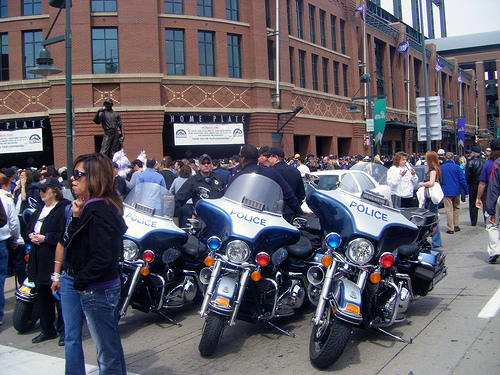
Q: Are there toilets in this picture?
A: No, there are no toilets.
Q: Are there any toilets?
A: No, there are no toilets.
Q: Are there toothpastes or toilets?
A: No, there are no toilets or toothpastes.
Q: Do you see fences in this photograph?
A: No, there are no fences.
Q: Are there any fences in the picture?
A: No, there are no fences.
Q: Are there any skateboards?
A: No, there are no skateboards.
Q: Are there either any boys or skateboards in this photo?
A: No, there are no skateboards or boys.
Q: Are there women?
A: Yes, there is a woman.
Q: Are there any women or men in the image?
A: Yes, there is a woman.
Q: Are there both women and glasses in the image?
A: Yes, there are both a woman and glasses.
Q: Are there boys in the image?
A: No, there are no boys.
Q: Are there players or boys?
A: No, there are no boys or players.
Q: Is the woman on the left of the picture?
A: Yes, the woman is on the left of the image.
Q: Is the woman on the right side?
A: No, the woman is on the left of the image.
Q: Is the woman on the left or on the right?
A: The woman is on the left of the image.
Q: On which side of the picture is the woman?
A: The woman is on the left of the image.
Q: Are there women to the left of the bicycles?
A: Yes, there is a woman to the left of the bicycles.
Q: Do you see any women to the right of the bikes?
A: No, the woman is to the left of the bikes.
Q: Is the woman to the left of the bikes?
A: Yes, the woman is to the left of the bikes.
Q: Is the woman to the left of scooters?
A: No, the woman is to the left of the bikes.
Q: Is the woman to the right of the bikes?
A: No, the woman is to the left of the bikes.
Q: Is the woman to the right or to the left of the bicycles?
A: The woman is to the left of the bicycles.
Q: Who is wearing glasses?
A: The woman is wearing glasses.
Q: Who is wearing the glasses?
A: The woman is wearing glasses.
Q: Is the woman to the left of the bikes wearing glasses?
A: Yes, the woman is wearing glasses.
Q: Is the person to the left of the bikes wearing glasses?
A: Yes, the woman is wearing glasses.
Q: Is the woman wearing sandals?
A: No, the woman is wearing glasses.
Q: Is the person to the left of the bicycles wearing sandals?
A: No, the woman is wearing glasses.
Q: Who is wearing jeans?
A: The woman is wearing jeans.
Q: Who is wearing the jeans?
A: The woman is wearing jeans.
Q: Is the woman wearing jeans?
A: Yes, the woman is wearing jeans.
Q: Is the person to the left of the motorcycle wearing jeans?
A: Yes, the woman is wearing jeans.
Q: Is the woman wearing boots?
A: No, the woman is wearing jeans.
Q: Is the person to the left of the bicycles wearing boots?
A: No, the woman is wearing jeans.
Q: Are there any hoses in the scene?
A: No, there are no hoses.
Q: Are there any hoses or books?
A: No, there are no hoses or books.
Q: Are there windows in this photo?
A: Yes, there is a window.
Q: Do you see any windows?
A: Yes, there is a window.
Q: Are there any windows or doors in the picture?
A: Yes, there is a window.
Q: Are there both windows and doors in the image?
A: No, there is a window but no doors.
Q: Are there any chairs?
A: No, there are no chairs.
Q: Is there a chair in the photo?
A: No, there are no chairs.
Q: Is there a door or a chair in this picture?
A: No, there are no chairs or doors.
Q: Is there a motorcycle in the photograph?
A: Yes, there is a motorcycle.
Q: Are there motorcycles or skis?
A: Yes, there is a motorcycle.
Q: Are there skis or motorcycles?
A: Yes, there is a motorcycle.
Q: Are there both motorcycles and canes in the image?
A: No, there is a motorcycle but no canes.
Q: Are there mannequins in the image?
A: No, there are no mannequins.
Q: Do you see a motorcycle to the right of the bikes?
A: Yes, there is a motorcycle to the right of the bikes.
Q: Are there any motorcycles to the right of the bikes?
A: Yes, there is a motorcycle to the right of the bikes.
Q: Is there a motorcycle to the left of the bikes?
A: No, the motorcycle is to the right of the bikes.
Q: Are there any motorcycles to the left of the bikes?
A: No, the motorcycle is to the right of the bikes.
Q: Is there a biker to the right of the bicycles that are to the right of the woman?
A: No, there is a motorcycle to the right of the bicycles.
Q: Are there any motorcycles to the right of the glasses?
A: Yes, there is a motorcycle to the right of the glasses.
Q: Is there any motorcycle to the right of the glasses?
A: Yes, there is a motorcycle to the right of the glasses.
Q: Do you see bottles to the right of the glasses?
A: No, there is a motorcycle to the right of the glasses.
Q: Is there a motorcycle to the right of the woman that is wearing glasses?
A: Yes, there is a motorcycle to the right of the woman.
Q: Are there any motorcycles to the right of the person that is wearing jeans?
A: Yes, there is a motorcycle to the right of the woman.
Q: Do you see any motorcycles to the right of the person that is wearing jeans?
A: Yes, there is a motorcycle to the right of the woman.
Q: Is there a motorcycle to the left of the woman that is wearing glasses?
A: No, the motorcycle is to the right of the woman.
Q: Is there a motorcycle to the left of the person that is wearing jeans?
A: No, the motorcycle is to the right of the woman.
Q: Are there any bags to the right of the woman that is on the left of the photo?
A: No, there is a motorcycle to the right of the woman.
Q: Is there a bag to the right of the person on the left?
A: No, there is a motorcycle to the right of the woman.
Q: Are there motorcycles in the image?
A: Yes, there is a motorcycle.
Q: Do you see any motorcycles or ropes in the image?
A: Yes, there is a motorcycle.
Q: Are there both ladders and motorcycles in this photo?
A: No, there is a motorcycle but no ladders.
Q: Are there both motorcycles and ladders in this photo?
A: No, there is a motorcycle but no ladders.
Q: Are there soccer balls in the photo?
A: No, there are no soccer balls.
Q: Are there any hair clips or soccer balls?
A: No, there are no soccer balls or hair clips.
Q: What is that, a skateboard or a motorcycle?
A: That is a motorcycle.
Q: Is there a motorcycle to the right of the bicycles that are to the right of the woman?
A: Yes, there is a motorcycle to the right of the bicycles.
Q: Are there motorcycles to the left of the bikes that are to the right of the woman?
A: No, the motorcycle is to the right of the bicycles.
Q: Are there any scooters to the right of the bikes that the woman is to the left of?
A: No, there is a motorcycle to the right of the bikes.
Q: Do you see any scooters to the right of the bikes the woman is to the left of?
A: No, there is a motorcycle to the right of the bikes.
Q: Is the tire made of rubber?
A: Yes, the tire is made of rubber.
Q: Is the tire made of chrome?
A: No, the tire is made of rubber.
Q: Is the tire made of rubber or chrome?
A: The tire is made of rubber.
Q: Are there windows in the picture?
A: Yes, there is a window.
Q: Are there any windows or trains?
A: Yes, there is a window.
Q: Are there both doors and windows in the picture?
A: No, there is a window but no doors.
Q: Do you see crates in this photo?
A: No, there are no crates.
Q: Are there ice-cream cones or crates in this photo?
A: No, there are no crates or ice-cream cones.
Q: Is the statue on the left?
A: Yes, the statue is on the left of the image.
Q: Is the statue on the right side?
A: No, the statue is on the left of the image.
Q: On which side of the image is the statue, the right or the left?
A: The statue is on the left of the image.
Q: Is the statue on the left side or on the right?
A: The statue is on the left of the image.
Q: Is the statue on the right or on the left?
A: The statue is on the left of the image.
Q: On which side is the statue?
A: The statue is on the left of the image.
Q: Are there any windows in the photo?
A: Yes, there is a window.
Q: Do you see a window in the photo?
A: Yes, there is a window.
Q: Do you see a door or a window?
A: Yes, there is a window.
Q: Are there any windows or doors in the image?
A: Yes, there is a window.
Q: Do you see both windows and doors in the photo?
A: No, there is a window but no doors.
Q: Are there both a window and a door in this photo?
A: No, there is a window but no doors.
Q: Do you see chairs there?
A: No, there are no chairs.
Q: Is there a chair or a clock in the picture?
A: No, there are no chairs or clocks.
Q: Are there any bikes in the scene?
A: Yes, there are bikes.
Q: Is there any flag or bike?
A: Yes, there are bikes.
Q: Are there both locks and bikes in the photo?
A: No, there are bikes but no locks.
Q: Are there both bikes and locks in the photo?
A: No, there are bikes but no locks.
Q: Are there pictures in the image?
A: No, there are no pictures.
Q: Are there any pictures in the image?
A: No, there are no pictures.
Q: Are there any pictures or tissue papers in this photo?
A: No, there are no pictures or tissue papers.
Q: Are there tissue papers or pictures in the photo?
A: No, there are no pictures or tissue papers.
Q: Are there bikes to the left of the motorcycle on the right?
A: Yes, there are bikes to the left of the motorbike.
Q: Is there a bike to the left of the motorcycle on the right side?
A: Yes, there are bikes to the left of the motorbike.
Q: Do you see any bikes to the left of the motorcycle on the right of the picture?
A: Yes, there are bikes to the left of the motorbike.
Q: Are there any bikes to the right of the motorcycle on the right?
A: No, the bikes are to the left of the motorcycle.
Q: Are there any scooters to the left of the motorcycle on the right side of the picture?
A: No, there are bikes to the left of the motorcycle.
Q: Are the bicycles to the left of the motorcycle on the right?
A: Yes, the bicycles are to the left of the motorcycle.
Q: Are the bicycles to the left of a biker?
A: No, the bicycles are to the left of the motorcycle.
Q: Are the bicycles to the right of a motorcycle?
A: No, the bicycles are to the left of a motorcycle.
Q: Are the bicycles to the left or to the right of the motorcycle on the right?
A: The bicycles are to the left of the motorcycle.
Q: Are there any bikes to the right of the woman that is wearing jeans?
A: Yes, there are bikes to the right of the woman.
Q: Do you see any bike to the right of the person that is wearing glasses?
A: Yes, there are bikes to the right of the woman.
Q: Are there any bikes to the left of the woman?
A: No, the bikes are to the right of the woman.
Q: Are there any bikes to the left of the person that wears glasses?
A: No, the bikes are to the right of the woman.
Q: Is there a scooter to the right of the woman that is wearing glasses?
A: No, there are bikes to the right of the woman.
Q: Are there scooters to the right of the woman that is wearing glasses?
A: No, there are bikes to the right of the woman.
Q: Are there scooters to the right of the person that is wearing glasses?
A: No, there are bikes to the right of the woman.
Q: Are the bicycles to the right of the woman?
A: Yes, the bicycles are to the right of the woman.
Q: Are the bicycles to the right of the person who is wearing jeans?
A: Yes, the bicycles are to the right of the woman.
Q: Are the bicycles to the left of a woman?
A: No, the bicycles are to the right of a woman.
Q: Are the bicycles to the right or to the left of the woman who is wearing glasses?
A: The bicycles are to the right of the woman.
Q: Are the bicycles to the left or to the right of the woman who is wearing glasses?
A: The bicycles are to the right of the woman.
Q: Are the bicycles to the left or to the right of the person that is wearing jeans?
A: The bicycles are to the right of the woman.